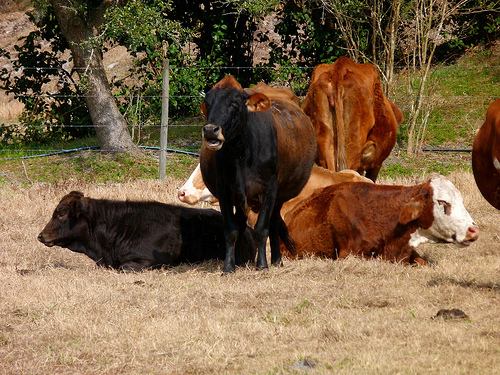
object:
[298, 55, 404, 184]
cow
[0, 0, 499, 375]
field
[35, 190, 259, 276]
cow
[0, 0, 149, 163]
tree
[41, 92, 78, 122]
leaf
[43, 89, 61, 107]
stem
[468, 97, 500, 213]
cow